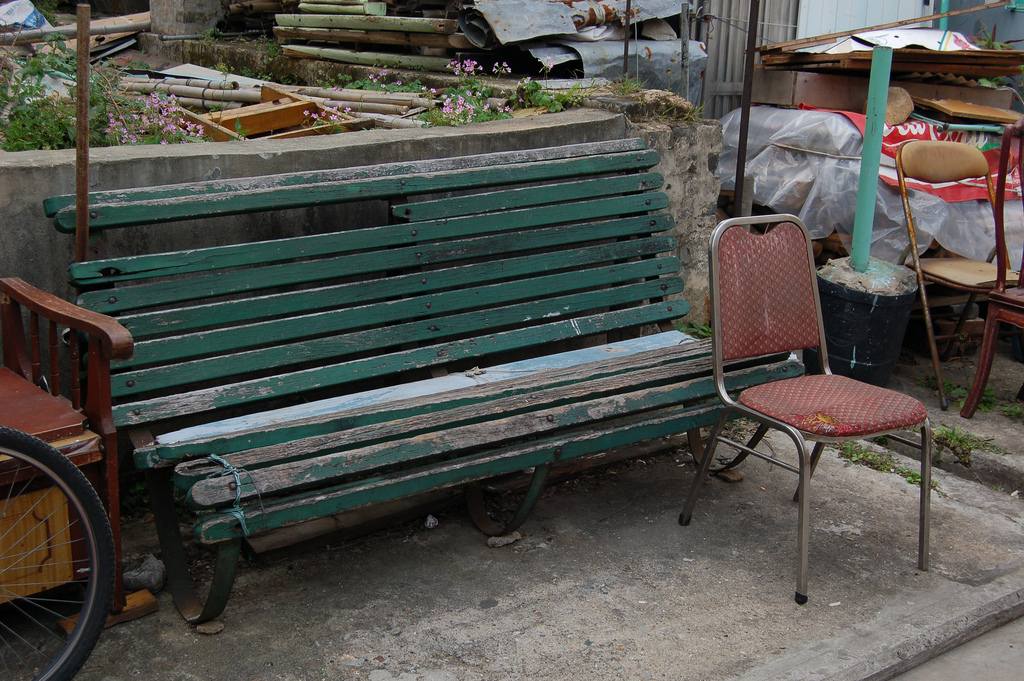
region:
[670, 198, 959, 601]
chair in front of the bench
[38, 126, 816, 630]
green wooden bench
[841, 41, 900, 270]
green pole in cement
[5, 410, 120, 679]
bike tire near a bench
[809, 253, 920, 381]
black bucket near the bench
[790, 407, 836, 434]
tear on the fabric seat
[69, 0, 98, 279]
wood pole near the bench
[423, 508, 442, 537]
crumpled paper under the bench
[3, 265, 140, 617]
wooden chair near the bench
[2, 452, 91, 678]
spokes of a bike tire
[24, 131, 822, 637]
A green wooden bench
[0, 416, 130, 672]
A black round wheel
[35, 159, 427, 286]
A missing piece of a green bench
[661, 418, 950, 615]
The legs of a chair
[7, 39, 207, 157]
Pink flowers and green leaves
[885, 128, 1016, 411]
Chair with beige cushions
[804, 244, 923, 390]
A pot is colored black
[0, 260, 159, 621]
Brown wooden arm of a chair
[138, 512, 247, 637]
Black leg of a bench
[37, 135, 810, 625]
bench is green and old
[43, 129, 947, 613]
chair sitting in front of bench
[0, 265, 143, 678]
bicycle wheel in front of brown bench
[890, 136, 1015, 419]
chair is light brown and rusty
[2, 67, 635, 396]
pile of logs behind concrete wall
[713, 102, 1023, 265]
red banner on top of white plastic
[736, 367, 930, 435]
worn edge on seat cushion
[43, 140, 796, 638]
the bench's green paint is faded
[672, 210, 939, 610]
a metal framed chair with red upholstery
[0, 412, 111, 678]
the wheel of a bicycle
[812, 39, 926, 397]
a green post is set in a lack bucket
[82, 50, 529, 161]
purple flowers are growing behind the bench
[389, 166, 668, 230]
this board in the bench back is broken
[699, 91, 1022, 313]
several objects are covered with plastic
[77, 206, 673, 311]
green wooden slat on the bench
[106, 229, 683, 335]
green wooden slat on the bench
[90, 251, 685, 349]
green wooden slat on the bench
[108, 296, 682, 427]
green wooden slat on the bench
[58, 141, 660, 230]
green wooden slat on the bench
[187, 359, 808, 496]
green wooden slat on the bench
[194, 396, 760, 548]
green wooden slat on the bench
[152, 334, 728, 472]
green wooden slat on the bench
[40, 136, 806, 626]
A worn green bench.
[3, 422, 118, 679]
Black rubber bicycle wheel.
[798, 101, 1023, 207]
Red coca cola banner with white lettering.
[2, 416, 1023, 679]
Grey concrete area in front of a bench.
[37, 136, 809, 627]
A worn green bench against a wall.